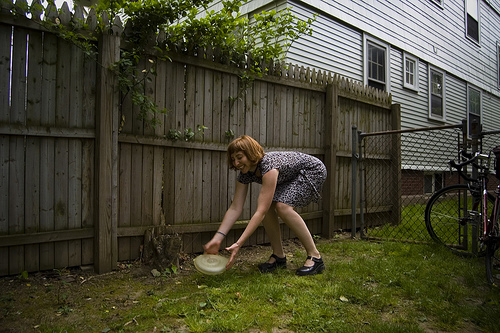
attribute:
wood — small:
[57, 2, 70, 269]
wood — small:
[43, 1, 58, 273]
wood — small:
[27, 2, 43, 274]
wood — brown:
[12, 2, 23, 278]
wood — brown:
[72, 7, 79, 274]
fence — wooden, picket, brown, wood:
[0, 1, 401, 276]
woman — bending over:
[205, 134, 327, 277]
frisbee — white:
[193, 253, 231, 273]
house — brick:
[241, 0, 500, 201]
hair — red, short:
[227, 136, 263, 165]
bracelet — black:
[217, 227, 228, 240]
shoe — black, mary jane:
[295, 252, 323, 275]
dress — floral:
[235, 153, 328, 208]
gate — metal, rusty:
[351, 129, 468, 251]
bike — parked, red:
[424, 135, 498, 254]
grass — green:
[70, 199, 497, 333]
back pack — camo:
[143, 224, 182, 265]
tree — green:
[80, 1, 316, 141]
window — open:
[464, 1, 481, 44]